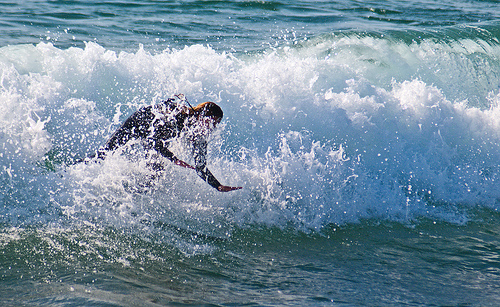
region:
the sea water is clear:
[267, 274, 282, 294]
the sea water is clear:
[297, 279, 324, 304]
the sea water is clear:
[306, 245, 326, 280]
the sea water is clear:
[292, 280, 302, 288]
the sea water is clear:
[283, 244, 308, 271]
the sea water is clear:
[294, 245, 312, 277]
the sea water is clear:
[286, 253, 301, 280]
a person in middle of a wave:
[94, 85, 253, 210]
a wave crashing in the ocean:
[4, 28, 490, 238]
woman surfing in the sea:
[90, 79, 251, 214]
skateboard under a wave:
[21, 148, 242, 263]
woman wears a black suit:
[87, 85, 254, 216]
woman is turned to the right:
[82, 79, 264, 221]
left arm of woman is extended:
[194, 143, 254, 198]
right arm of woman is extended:
[139, 117, 198, 182]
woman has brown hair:
[153, 86, 230, 148]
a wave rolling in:
[3, 21, 494, 259]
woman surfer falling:
[123, 105, 260, 201]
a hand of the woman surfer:
[215, 174, 275, 201]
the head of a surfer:
[189, 99, 229, 136]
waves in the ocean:
[309, 19, 494, 226]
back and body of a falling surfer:
[107, 103, 179, 144]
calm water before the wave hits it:
[340, 243, 436, 304]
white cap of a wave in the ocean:
[371, 54, 479, 137]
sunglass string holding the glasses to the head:
[172, 85, 195, 111]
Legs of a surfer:
[84, 137, 172, 199]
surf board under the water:
[142, 202, 277, 244]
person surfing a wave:
[64, 87, 265, 215]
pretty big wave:
[3, 38, 487, 285]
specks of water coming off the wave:
[300, 186, 357, 241]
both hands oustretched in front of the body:
[153, 133, 243, 201]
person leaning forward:
[30, 91, 287, 238]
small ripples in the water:
[439, 224, 498, 281]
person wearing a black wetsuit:
[63, 81, 240, 243]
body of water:
[1, 1, 496, 303]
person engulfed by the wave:
[50, 51, 272, 218]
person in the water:
[53, 95, 258, 216]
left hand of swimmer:
[198, 168, 261, 203]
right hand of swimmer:
[155, 143, 203, 178]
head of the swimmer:
[181, 87, 236, 135]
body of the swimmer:
[117, 85, 209, 142]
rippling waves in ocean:
[266, 41, 431, 206]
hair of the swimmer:
[192, 85, 220, 115]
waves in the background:
[24, 4, 288, 48]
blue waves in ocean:
[264, 207, 467, 304]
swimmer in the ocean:
[26, 83, 263, 188]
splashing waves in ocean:
[40, 154, 138, 221]